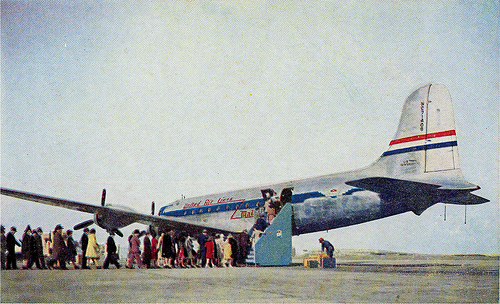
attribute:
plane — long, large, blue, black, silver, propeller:
[170, 69, 480, 265]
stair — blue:
[238, 196, 302, 276]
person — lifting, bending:
[255, 222, 371, 277]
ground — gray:
[197, 269, 236, 298]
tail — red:
[423, 126, 455, 144]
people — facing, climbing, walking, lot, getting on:
[12, 201, 241, 282]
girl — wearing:
[68, 217, 109, 260]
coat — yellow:
[84, 232, 109, 260]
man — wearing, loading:
[195, 220, 214, 238]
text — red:
[205, 186, 237, 214]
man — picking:
[294, 232, 338, 271]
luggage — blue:
[310, 256, 341, 274]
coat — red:
[204, 240, 217, 247]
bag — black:
[307, 258, 320, 273]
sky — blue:
[187, 35, 254, 80]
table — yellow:
[287, 246, 327, 265]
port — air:
[33, 213, 427, 298]